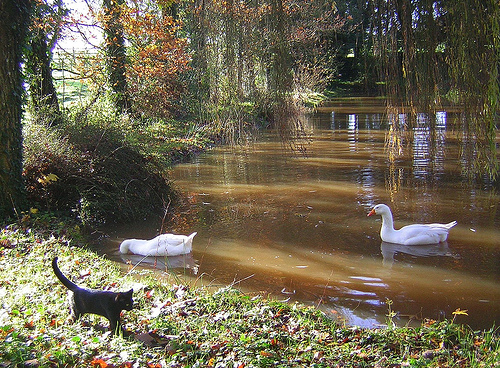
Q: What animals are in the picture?
A: Two geese and a cat.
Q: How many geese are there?
A: Two.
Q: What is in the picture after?
A: The geese.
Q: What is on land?
A: A cat.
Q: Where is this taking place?
A: Outside near a river.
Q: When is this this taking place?
A: Daytime.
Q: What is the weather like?
A: It's sunny.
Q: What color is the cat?
A: Black.